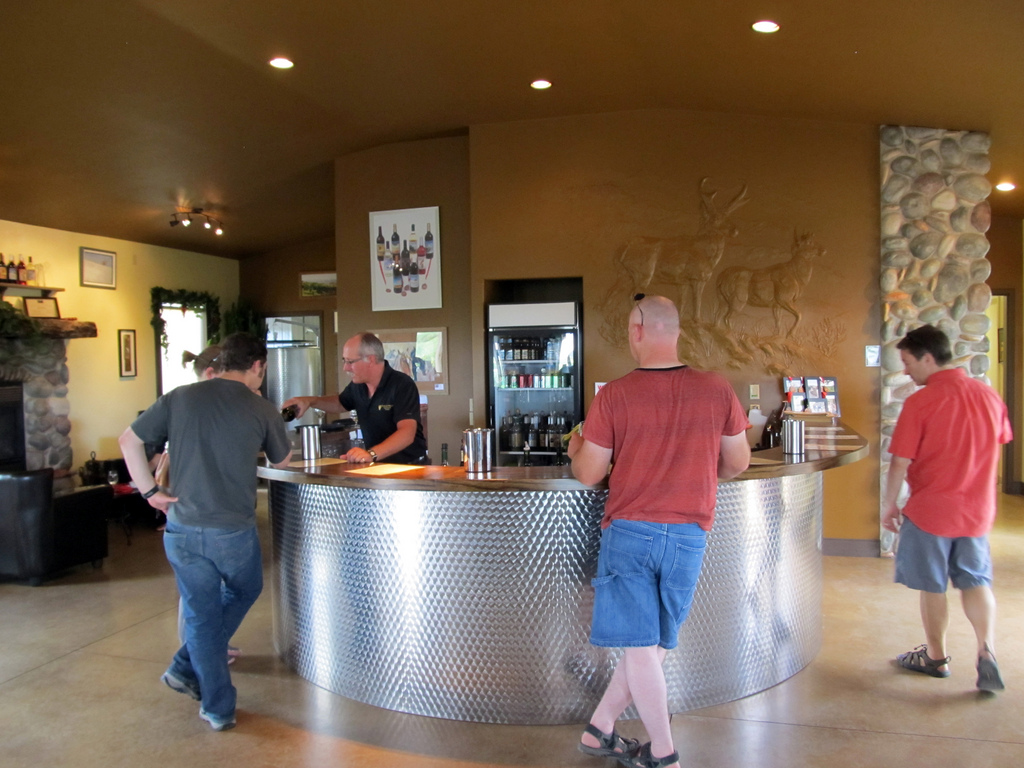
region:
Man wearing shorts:
[576, 503, 713, 656]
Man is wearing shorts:
[576, 498, 713, 653]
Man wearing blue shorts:
[579, 501, 719, 656]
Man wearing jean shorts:
[582, 500, 710, 659]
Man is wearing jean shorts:
[585, 500, 715, 662]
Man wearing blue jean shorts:
[579, 497, 722, 660]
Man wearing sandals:
[564, 705, 710, 766]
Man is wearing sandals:
[558, 708, 695, 765]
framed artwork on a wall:
[363, 203, 452, 318]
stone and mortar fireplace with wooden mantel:
[0, 312, 95, 484]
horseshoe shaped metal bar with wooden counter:
[253, 424, 868, 728]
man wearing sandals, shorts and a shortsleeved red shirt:
[874, 319, 1017, 694]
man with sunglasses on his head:
[559, 285, 756, 764]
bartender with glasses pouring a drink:
[269, 331, 432, 467]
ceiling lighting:
[176, 211, 234, 246]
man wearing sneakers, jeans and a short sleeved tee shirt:
[116, 335, 297, 735]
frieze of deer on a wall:
[591, 170, 833, 376]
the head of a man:
[605, 230, 768, 393]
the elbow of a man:
[544, 417, 628, 498]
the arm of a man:
[523, 347, 710, 513]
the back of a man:
[555, 247, 765, 554]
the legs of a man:
[564, 537, 724, 738]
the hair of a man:
[617, 277, 713, 379]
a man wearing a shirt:
[125, 282, 338, 545]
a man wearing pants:
[105, 435, 382, 750]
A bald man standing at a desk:
[569, 300, 753, 762]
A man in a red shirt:
[886, 319, 1013, 692]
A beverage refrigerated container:
[491, 297, 578, 471]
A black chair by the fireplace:
[0, 467, 119, 584]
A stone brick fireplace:
[0, 326, 98, 469]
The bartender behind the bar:
[332, 337, 424, 465]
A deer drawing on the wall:
[615, 187, 832, 315]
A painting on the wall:
[364, 199, 450, 318]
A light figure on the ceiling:
[178, 198, 235, 247]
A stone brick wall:
[871, 139, 998, 321]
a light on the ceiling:
[531, 76, 551, 92]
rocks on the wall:
[34, 328, 67, 475]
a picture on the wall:
[366, 209, 442, 307]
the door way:
[154, 304, 199, 375]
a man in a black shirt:
[337, 345, 417, 451]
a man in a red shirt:
[581, 297, 741, 765]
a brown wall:
[474, 129, 883, 365]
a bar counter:
[259, 443, 855, 700]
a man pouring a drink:
[280, 331, 427, 461]